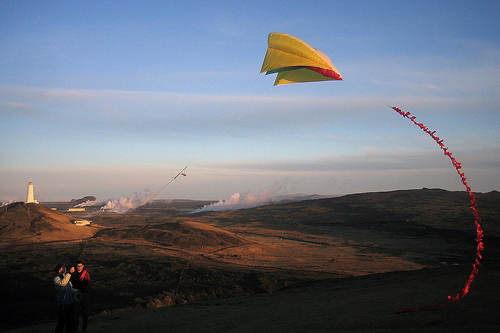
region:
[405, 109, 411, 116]
red tassel on kite tail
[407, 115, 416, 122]
red tassel on kite tail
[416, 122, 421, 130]
red tassel on kite tail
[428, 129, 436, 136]
red tassel on kite tail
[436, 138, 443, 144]
red tassel on kite tail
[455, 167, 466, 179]
red tassel on kite tail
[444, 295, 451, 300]
red tassel on kite tail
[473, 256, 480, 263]
red tassel on kite tail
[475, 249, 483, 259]
red tassel on kite tail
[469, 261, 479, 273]
red tassel on kite tail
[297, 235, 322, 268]
part of a groumd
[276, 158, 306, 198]
par tof a cloud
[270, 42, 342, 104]
this is a kite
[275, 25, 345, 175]
the kite is yellow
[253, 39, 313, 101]
the kite is yellow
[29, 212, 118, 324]
this is a family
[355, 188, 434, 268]
this is a mountain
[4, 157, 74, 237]
this is a building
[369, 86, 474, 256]
this is a long ribbon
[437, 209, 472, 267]
the ribbon is red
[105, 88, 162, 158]
these are clouds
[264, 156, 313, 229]
the clouds are white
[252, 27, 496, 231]
Kite flying in the air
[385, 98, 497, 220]
Tail on the kite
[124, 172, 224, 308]
Line holding the kite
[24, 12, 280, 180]
The sky is blue with some clouds.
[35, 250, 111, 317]
People flying the kite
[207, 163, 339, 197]
Fog coming from the ground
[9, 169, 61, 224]
Hill with a lighthouse on it.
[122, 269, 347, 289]
Small trees at the bottom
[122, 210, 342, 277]
Rolling hills beside the valley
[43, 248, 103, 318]
Sun shining on their faces.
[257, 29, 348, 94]
yellow kite in the sky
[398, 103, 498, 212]
red tail on kite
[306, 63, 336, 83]
red back section of kite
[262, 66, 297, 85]
green under section of kite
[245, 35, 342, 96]
curved yellow kite in air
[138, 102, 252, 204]
long kite string attached to kite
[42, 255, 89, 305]
two people flying kite on ground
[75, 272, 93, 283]
red jacket on man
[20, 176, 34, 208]
large white building in back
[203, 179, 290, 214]
white water hitting side of cliffs